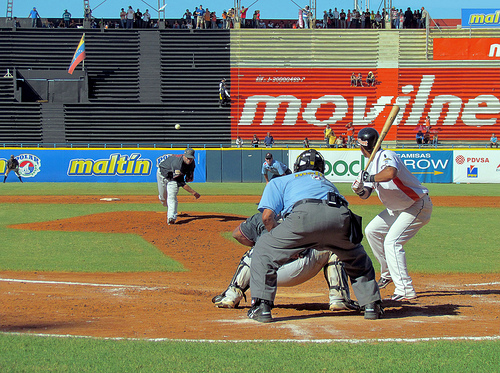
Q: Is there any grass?
A: Yes, there is grass.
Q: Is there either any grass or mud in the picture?
A: Yes, there is grass.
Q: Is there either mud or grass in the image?
A: Yes, there is grass.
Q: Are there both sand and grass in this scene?
A: No, there is grass but no sand.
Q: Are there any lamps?
A: No, there are no lamps.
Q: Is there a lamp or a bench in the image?
A: No, there are no lamps or benches.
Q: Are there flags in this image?
A: Yes, there is a flag.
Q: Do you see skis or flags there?
A: Yes, there is a flag.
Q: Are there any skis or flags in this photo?
A: Yes, there is a flag.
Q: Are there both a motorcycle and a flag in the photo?
A: No, there is a flag but no motorcycles.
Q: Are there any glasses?
A: No, there are no glasses.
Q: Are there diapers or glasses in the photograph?
A: No, there are no glasses or diapers.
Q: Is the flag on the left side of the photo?
A: Yes, the flag is on the left of the image.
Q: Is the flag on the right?
A: No, the flag is on the left of the image.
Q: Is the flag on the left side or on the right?
A: The flag is on the left of the image.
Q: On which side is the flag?
A: The flag is on the left of the image.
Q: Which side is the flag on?
A: The flag is on the left of the image.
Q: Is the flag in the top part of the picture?
A: Yes, the flag is in the top of the image.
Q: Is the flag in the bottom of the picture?
A: No, the flag is in the top of the image.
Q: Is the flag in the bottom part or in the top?
A: The flag is in the top of the image.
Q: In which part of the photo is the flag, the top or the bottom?
A: The flag is in the top of the image.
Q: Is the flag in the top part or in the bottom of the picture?
A: The flag is in the top of the image.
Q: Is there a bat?
A: Yes, there is a bat.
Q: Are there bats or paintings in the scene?
A: Yes, there is a bat.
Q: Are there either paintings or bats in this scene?
A: Yes, there is a bat.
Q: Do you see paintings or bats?
A: Yes, there is a bat.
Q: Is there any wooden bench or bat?
A: Yes, there is a wood bat.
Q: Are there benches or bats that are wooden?
A: Yes, the bat is wooden.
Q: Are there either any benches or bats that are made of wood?
A: Yes, the bat is made of wood.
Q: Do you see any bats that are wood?
A: Yes, there is a wood bat.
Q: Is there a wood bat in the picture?
A: Yes, there is a wood bat.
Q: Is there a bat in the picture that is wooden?
A: Yes, there is a bat that is wooden.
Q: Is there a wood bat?
A: Yes, there is a bat that is made of wood.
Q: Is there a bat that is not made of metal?
A: Yes, there is a bat that is made of wood.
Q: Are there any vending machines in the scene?
A: No, there are no vending machines.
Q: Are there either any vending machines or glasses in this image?
A: No, there are no vending machines or glasses.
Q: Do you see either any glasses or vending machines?
A: No, there are no vending machines or glasses.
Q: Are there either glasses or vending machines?
A: No, there are no vending machines or glasses.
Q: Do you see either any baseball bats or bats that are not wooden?
A: No, there is a bat but it is wooden.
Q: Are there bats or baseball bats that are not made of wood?
A: No, there is a bat but it is made of wood.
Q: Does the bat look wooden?
A: Yes, the bat is wooden.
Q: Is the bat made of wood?
A: Yes, the bat is made of wood.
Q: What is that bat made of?
A: The bat is made of wood.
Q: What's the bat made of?
A: The bat is made of wood.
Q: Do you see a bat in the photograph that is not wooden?
A: No, there is a bat but it is wooden.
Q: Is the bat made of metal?
A: No, the bat is made of wood.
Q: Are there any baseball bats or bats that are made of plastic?
A: No, there is a bat but it is made of wood.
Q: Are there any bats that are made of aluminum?
A: No, there is a bat but it is made of wood.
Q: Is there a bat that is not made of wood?
A: No, there is a bat but it is made of wood.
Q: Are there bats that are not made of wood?
A: No, there is a bat but it is made of wood.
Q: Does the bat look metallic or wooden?
A: The bat is wooden.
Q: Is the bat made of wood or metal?
A: The bat is made of wood.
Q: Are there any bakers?
A: No, there are no bakers.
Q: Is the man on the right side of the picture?
A: Yes, the man is on the right of the image.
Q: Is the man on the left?
A: No, the man is on the right of the image.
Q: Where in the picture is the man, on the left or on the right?
A: The man is on the right of the image.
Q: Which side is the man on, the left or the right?
A: The man is on the right of the image.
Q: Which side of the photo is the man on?
A: The man is on the right of the image.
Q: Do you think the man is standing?
A: Yes, the man is standing.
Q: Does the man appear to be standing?
A: Yes, the man is standing.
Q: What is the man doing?
A: The man is standing.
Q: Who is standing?
A: The man is standing.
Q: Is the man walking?
A: No, the man is standing.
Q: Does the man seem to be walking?
A: No, the man is standing.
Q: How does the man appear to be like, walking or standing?
A: The man is standing.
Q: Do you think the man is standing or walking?
A: The man is standing.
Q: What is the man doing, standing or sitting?
A: The man is standing.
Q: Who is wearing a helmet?
A: The man is wearing a helmet.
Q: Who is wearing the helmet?
A: The man is wearing a helmet.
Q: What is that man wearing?
A: The man is wearing a helmet.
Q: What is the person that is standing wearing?
A: The man is wearing a helmet.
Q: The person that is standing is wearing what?
A: The man is wearing a helmet.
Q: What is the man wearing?
A: The man is wearing a helmet.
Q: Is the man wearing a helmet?
A: Yes, the man is wearing a helmet.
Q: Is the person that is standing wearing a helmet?
A: Yes, the man is wearing a helmet.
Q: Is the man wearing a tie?
A: No, the man is wearing a helmet.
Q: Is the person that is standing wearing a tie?
A: No, the man is wearing a helmet.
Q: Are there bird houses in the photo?
A: No, there are no bird houses.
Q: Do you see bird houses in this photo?
A: No, there are no bird houses.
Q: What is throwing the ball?
A: The pitcher is throwing the ball.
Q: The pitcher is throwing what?
A: The pitcher is throwing the ball.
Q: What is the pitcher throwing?
A: The pitcher is throwing the ball.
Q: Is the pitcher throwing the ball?
A: Yes, the pitcher is throwing the ball.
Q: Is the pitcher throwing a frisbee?
A: No, the pitcher is throwing the ball.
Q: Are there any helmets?
A: Yes, there is a helmet.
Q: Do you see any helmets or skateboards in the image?
A: Yes, there is a helmet.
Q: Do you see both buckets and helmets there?
A: No, there is a helmet but no buckets.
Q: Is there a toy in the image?
A: No, there are no toys.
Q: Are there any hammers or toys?
A: No, there are no toys or hammers.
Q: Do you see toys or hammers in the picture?
A: No, there are no toys or hammers.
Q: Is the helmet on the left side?
A: No, the helmet is on the right of the image.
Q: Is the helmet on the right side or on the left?
A: The helmet is on the right of the image.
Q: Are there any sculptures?
A: No, there are no sculptures.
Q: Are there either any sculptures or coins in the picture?
A: No, there are no sculptures or coins.